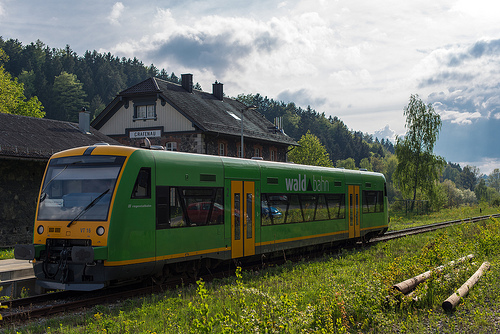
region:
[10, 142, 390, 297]
A green and yellow train.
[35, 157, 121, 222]
A windshield of a train.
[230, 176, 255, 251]
The doors of a train.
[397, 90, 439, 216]
A thin tall tree.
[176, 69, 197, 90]
The chimney of a building.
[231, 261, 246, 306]
A green weed in the grass.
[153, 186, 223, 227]
A window on the train.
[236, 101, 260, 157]
A light pole in the daytime.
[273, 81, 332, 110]
A cloud in the sky.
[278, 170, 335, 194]
Writing on the side of a train.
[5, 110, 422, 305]
green train on tracks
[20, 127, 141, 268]
train has yellow trim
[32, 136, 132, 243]
train has square window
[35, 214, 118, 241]
train has two headlights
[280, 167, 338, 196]
train has white writing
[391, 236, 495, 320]
two logs laying in grass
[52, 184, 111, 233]
train has windshield wiper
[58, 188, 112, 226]
windshield wiper is black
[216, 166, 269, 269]
train has yellow door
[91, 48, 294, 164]
building has dark brown roof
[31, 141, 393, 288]
Train on the tracks.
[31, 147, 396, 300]
Green and yellow train.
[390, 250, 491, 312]
Brown logs on the grass.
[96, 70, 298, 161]
House in the background.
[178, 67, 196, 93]
chimney on the roof.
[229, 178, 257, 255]
Yellow doors on the train.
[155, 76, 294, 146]
Black roof on the house.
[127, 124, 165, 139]
Sign on the building.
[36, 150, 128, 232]
Window on the front of the train.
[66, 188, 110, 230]
Black wiper on the window.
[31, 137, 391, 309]
a train engine on the train tracks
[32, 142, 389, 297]
a green color train engine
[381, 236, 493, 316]
some small plants surrounding the timbers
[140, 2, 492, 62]
the sky is shiny and cloudy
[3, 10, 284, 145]
bushes of trees behind the buildings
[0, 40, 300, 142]
roof of buildings in front of the bushes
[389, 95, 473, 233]
a tree with green leaves near the train tracks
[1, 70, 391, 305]
a train is moving in front of the buildings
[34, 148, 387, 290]
doors of the train are painted in yellow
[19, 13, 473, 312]
this is a rural setting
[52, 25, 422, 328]
this is beside a forest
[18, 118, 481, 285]
this is a railroad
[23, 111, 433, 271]
this is a train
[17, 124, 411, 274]
the train is a passenger one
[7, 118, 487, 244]
the train is yellow and green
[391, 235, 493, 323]
these are logs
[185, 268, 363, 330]
there are wildflowers here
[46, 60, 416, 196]
this is a building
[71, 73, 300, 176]
this is a house